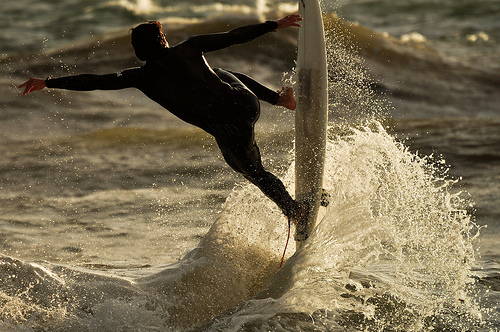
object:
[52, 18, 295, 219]
wetsuit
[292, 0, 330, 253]
surfboard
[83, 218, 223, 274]
water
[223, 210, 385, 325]
wave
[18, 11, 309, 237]
man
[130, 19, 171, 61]
head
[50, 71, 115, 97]
arm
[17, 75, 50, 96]
hand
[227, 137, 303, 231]
leg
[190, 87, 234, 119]
black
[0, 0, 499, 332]
ocean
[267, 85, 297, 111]
foot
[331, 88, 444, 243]
seaspray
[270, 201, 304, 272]
tethercord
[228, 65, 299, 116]
legs